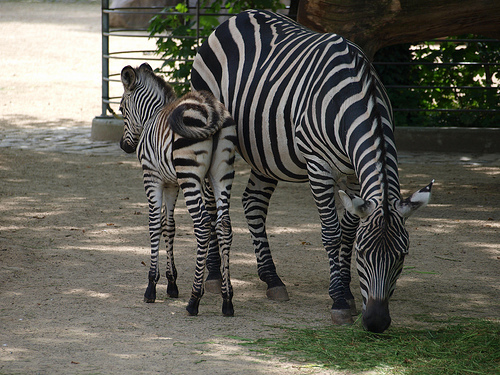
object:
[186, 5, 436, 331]
zebras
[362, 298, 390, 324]
nose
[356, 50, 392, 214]
mane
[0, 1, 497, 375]
ground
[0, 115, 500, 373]
dirt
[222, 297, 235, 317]
small hoof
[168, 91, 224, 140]
tail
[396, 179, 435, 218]
ear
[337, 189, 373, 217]
ear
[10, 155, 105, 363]
gravel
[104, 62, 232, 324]
zebra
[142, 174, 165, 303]
legs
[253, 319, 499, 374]
grass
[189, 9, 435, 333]
adult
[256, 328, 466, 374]
lawn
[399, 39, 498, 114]
bush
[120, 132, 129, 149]
snout